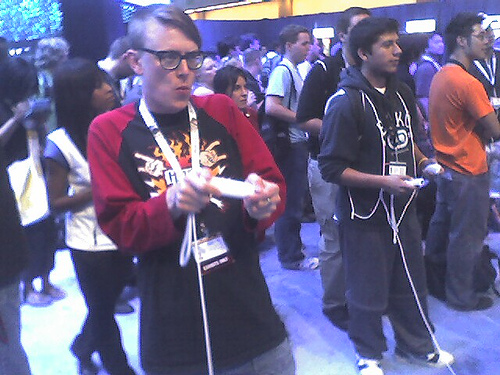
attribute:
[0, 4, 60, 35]
trees — upper left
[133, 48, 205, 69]
glasses — black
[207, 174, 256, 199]
controller — white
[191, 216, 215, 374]
cord — white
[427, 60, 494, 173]
shirt — orange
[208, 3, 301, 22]
paint — yellow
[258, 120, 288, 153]
bag — black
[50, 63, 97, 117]
hair — black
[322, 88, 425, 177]
sweatshirt — black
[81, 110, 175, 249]
sleeve — red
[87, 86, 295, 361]
shirt — red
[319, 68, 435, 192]
hoodie — black